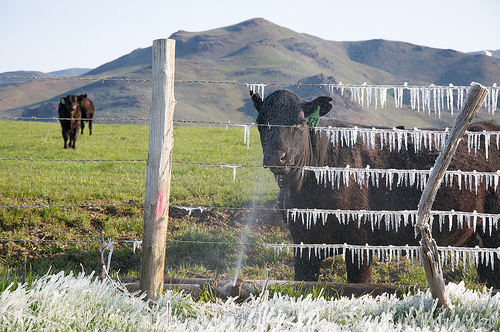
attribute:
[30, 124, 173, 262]
grass — green, cut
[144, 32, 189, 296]
pole — wooden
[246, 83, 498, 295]
cow — brown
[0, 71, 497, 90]
wire — metal, long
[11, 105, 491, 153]
wire — long, strand, metal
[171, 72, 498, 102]
wire — metal, strand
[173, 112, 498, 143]
wire — metal, strand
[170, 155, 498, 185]
wire — metal, strand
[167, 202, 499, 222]
wire — metal, strand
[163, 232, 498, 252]
wire —  metal, strand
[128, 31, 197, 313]
post — wooden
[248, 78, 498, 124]
wire — strand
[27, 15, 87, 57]
sky — clear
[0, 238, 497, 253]
wire — strand, long, metal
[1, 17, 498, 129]
mountains — brown